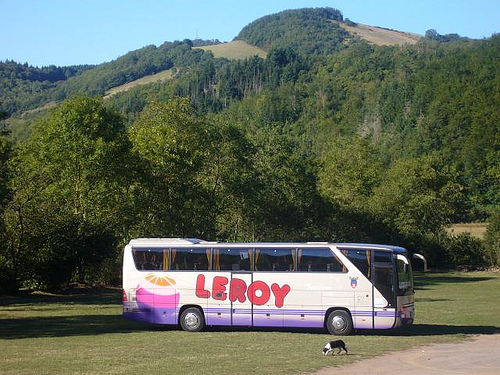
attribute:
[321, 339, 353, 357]
dog — white, black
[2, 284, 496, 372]
field — grassy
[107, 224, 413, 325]
bus — charter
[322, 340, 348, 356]
dog — white, black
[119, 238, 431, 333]
bus — white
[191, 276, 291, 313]
lettering — red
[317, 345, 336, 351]
markings — white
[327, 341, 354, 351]
markings — black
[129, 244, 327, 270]
windows — tinted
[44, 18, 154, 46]
skies — blue, clear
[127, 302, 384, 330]
stripes — purple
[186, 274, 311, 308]
logo — blue, red